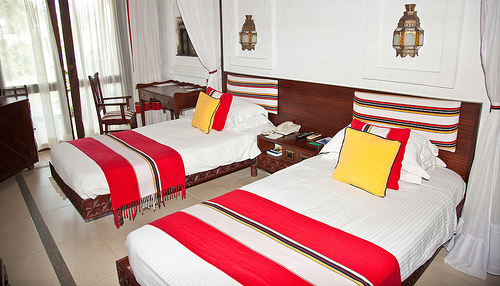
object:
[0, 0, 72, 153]
curtains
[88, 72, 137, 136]
chair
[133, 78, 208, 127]
desk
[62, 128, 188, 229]
blanket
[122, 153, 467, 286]
bedspread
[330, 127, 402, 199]
pillow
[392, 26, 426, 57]
light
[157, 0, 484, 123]
wall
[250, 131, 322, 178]
table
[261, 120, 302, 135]
phone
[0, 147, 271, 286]
floor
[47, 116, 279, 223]
bed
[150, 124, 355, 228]
twin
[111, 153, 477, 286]
bed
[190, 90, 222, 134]
pillow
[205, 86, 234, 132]
pillow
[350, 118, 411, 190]
pillow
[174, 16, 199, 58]
art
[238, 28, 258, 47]
light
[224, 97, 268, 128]
pillow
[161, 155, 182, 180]
red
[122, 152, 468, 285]
sheet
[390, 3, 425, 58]
lamp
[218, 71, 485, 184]
headboard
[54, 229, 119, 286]
tile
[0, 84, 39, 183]
dresser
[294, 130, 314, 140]
remote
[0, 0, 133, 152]
window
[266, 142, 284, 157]
stand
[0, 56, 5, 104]
tv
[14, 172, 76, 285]
stripe